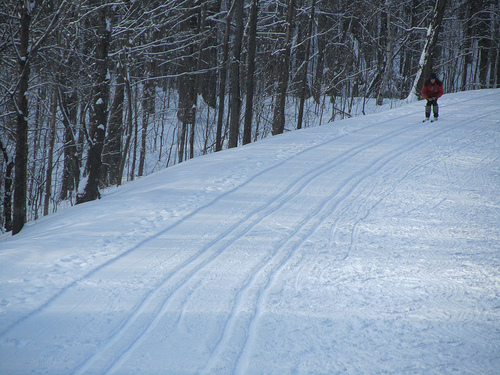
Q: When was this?
A: Daytime.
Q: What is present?
A: A person.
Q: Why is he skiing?
A: To have fun.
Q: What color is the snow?
A: White.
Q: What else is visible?
A: Trees.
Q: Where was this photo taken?
A: In the snow.